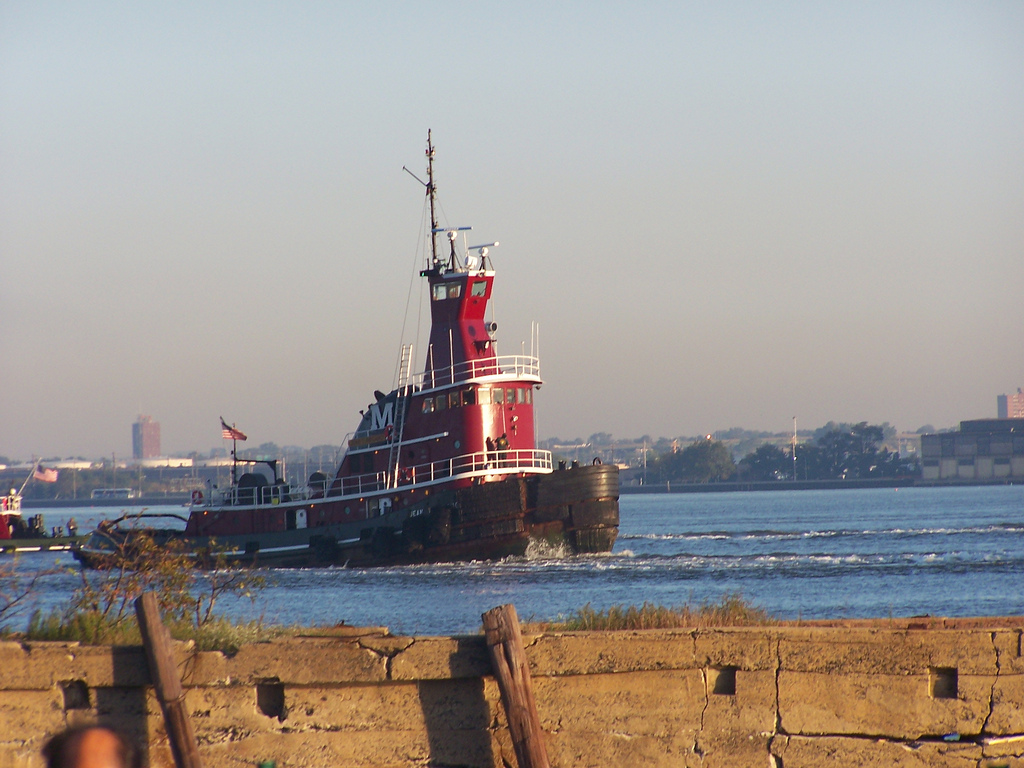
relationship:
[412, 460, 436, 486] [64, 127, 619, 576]
man on boat